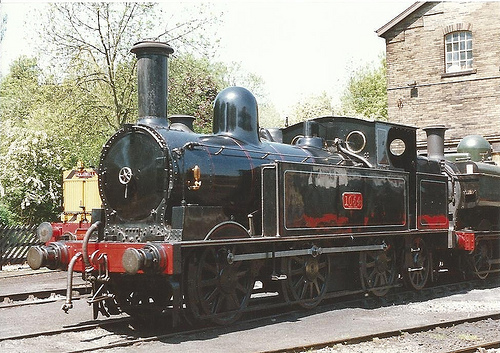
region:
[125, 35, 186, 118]
smoke stack on the engine car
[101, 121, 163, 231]
front of train is round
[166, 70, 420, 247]
train car is black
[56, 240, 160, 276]
bumper on train is red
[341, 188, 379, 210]
red plate on the side of train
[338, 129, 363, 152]
window is circle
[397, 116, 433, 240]
door to engine car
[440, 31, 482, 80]
window in the building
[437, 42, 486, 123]
building is made of brown shades of bricks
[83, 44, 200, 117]
trees on the side of the train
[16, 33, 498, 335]
THE TRAIN IS BLACK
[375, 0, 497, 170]
BUILDING IS BROWN AND MADE OF BRICKS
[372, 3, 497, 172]
THE BUILDING IS STONE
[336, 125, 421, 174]
THE WINDOW IS ROUND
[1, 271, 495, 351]
THE TRAIN IS ON TRACKS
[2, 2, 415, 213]
THE TREES ARE GREEN AND LEAFY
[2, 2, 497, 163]
THE BRIGHT SKY IS WHITE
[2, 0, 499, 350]
THE DAY IS VERY SUNNY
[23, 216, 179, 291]
THE FRONT OF THE TRAIN IS RED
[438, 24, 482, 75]
THE WINDOW IS ON THE BUILDING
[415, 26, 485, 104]
window on a building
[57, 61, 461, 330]
black train on tracks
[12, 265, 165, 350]
choo choo train tracks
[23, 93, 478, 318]
black choo choo train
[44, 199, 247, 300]
red paint on black train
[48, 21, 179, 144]
one tree in the back of a train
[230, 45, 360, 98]
blue sky on sunny day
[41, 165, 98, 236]
a sign next to a train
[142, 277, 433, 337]
four wheels in a row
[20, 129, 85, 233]
bushes in the background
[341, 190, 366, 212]
number on side of train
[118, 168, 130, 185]
wheel on front of train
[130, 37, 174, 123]
stack on top of train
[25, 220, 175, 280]
front end of black train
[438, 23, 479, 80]
window on brick building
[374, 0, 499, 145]
brick building with a window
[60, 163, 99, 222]
yellow building next to train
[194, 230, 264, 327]
large front wheel of train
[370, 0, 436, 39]
roof line of brick building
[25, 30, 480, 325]
A locomotive is sitting at the station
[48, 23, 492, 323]
A locomotive is coming through a station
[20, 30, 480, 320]
A locomotive is arriving at a station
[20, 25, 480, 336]
An old locomotive is on display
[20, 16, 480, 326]
Historical locomotive in a train yard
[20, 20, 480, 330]
An old steam powered railroad engine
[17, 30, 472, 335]
A locomotive is on the railroad tracks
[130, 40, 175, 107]
The smokestack on the locomotive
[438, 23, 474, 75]
A window on a building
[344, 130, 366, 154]
The window on a locomotive